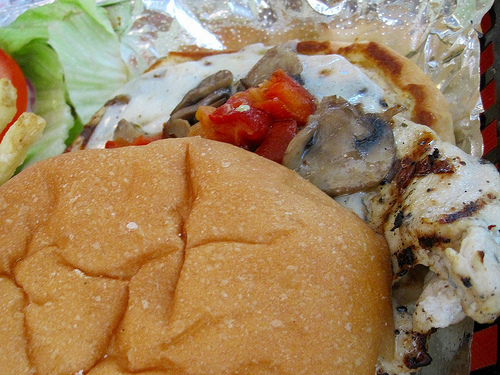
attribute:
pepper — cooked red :
[194, 68, 316, 165]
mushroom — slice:
[170, 68, 234, 123]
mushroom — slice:
[236, 44, 307, 91]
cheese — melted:
[74, 36, 499, 370]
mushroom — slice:
[282, 95, 404, 195]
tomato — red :
[255, 70, 322, 127]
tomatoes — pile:
[218, 81, 301, 146]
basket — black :
[476, 18, 496, 173]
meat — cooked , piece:
[312, 87, 499, 302]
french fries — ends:
[2, 73, 54, 180]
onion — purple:
[24, 72, 38, 112]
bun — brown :
[3, 135, 395, 372]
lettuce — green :
[1, 1, 139, 165]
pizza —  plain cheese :
[424, 32, 472, 70]